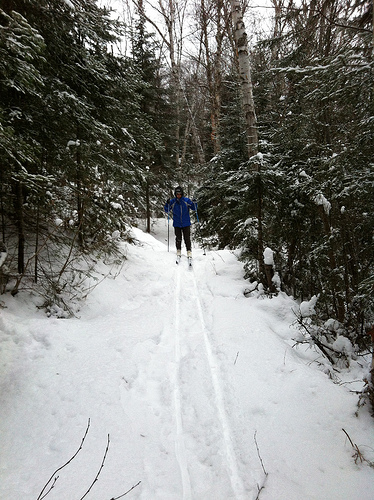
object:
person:
[170, 176, 197, 260]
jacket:
[169, 195, 190, 223]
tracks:
[110, 332, 154, 366]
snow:
[174, 430, 232, 456]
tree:
[0, 11, 105, 239]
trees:
[124, 74, 171, 228]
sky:
[153, 2, 274, 58]